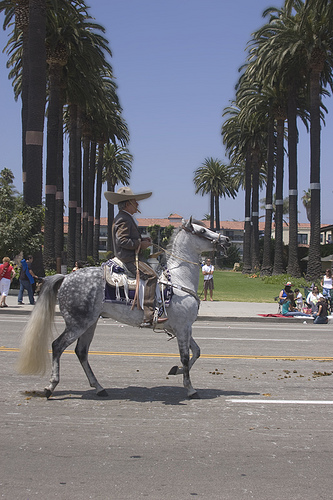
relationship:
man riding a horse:
[95, 180, 170, 333] [48, 220, 238, 408]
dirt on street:
[203, 363, 331, 389] [115, 327, 324, 494]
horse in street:
[48, 220, 238, 408] [115, 327, 324, 494]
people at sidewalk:
[254, 255, 331, 324] [175, 294, 277, 329]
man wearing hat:
[95, 180, 170, 333] [95, 177, 158, 209]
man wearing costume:
[95, 180, 170, 333] [108, 214, 170, 335]